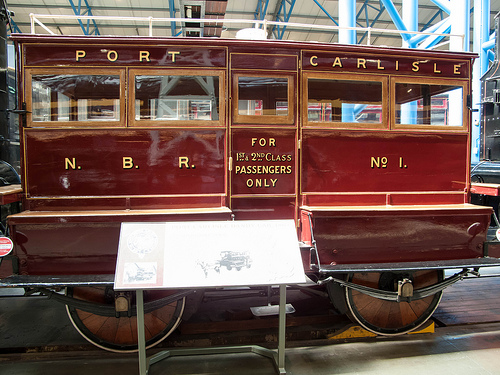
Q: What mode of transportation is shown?
A: Train.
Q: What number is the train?
A: 1.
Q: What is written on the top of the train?
A: Port Carlisle.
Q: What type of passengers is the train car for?
A: 1st and 2nd class.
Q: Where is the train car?
A: Museum.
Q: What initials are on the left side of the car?
A: N. B. R.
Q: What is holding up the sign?
A: Poles.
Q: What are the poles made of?
A: Metal.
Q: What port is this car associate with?
A: Carlisle.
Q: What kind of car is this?
A: Passenger Car.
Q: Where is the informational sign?
A: In front.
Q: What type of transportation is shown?
A: Trolley.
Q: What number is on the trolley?
A: 1.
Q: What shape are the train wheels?
A: Circle.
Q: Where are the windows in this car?
A: Top and all around.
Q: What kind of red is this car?
A: Dark red.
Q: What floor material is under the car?
A: Wood.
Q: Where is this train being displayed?
A: A museum.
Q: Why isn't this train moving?
A: It's on display.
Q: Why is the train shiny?
A: It is polished.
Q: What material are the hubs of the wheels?
A: Wood.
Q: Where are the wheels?
A: Under the cart.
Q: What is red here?
A: The cart.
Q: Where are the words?
A: On the wagon.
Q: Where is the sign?
A: On poles.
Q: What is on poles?
A: A sign.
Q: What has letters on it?
A: The cart.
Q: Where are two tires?
A: On the cart.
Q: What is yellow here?
A: Tire stops.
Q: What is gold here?
A: The letters.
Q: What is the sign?
A: Information plate.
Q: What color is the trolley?
A: Red.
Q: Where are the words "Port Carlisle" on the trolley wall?
A: The top.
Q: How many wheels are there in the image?
A: 2.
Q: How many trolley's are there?
A: 1.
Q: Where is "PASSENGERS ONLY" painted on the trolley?
A: The door.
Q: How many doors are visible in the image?
A: 1.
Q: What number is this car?
A: 1.